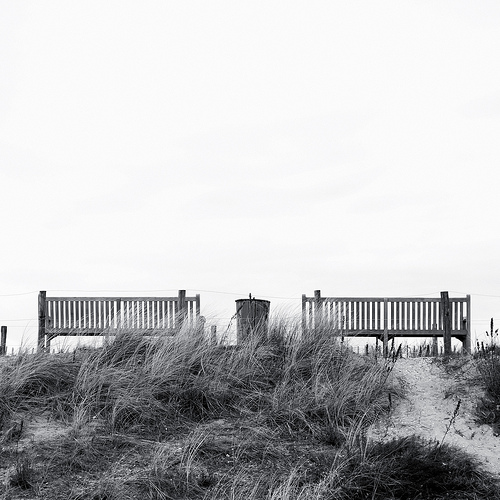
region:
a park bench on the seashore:
[302, 289, 474, 361]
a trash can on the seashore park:
[234, 296, 273, 354]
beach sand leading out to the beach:
[380, 354, 499, 469]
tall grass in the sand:
[1, 334, 403, 499]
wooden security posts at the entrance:
[440, 289, 454, 366]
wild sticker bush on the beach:
[472, 317, 499, 392]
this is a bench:
[5, 268, 232, 385]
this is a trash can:
[218, 260, 278, 356]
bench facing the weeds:
[3, 248, 230, 371]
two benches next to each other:
[8, 242, 498, 366]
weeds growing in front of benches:
[32, 294, 388, 494]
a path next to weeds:
[345, 340, 499, 482]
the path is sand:
[335, 328, 497, 483]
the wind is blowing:
[29, 289, 426, 499]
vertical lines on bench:
[20, 277, 201, 340]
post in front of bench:
[431, 283, 464, 355]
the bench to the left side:
[29, 290, 210, 344]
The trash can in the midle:
[228, 284, 291, 357]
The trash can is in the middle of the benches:
[229, 278, 278, 346]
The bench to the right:
[291, 285, 481, 350]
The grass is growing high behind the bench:
[2, 307, 462, 497]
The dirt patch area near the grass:
[378, 351, 494, 479]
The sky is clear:
[7, 7, 494, 347]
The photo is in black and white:
[8, 5, 498, 462]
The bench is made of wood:
[26, 287, 223, 367]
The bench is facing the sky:
[299, 285, 477, 368]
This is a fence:
[24, 280, 204, 351]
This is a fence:
[294, 280, 494, 361]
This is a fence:
[32, 277, 220, 374]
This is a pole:
[27, 280, 52, 365]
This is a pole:
[170, 282, 191, 348]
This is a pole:
[306, 280, 330, 357]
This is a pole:
[461, 285, 478, 377]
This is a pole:
[374, 287, 393, 360]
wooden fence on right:
[302, 280, 483, 371]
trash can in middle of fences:
[220, 283, 270, 350]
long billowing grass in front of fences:
[62, 333, 429, 442]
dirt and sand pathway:
[370, 355, 465, 462]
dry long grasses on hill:
[125, 368, 343, 462]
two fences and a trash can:
[25, 248, 482, 356]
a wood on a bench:
[76, 296, 83, 335]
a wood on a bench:
[97, 303, 112, 330]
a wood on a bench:
[150, 298, 160, 322]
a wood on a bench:
[168, 301, 178, 326]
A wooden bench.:
[29, 284, 210, 359]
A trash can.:
[236, 284, 285, 361]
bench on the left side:
[31, 282, 203, 357]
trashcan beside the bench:
[233, 294, 270, 340]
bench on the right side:
[298, 286, 473, 353]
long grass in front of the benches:
[5, 303, 451, 490]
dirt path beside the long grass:
[373, 350, 488, 460]